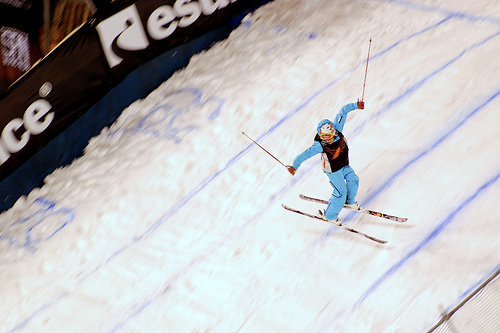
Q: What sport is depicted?
A: Skiing.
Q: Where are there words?
A: Wall on left.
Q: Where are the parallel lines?
A: In the snow.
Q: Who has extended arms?
A: Skier.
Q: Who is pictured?
A: A skier.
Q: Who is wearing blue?
A: The skier.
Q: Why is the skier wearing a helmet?
A: For protection.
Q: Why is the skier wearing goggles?
A: For protection.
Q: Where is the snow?
A: On the ground.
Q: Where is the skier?
A: In the air.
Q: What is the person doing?
A: Skiing.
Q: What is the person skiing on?
A: Snow.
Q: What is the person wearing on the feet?
A: Skis.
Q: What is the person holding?
A: Ski poles.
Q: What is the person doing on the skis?
A: Jumping in the air.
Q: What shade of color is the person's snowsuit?
A: Pastel blue snowsuit.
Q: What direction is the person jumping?
A: Right.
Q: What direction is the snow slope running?
A: Downhill.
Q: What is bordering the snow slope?
A: Blue and black banner fence.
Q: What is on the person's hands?
A: Gloves.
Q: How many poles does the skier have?
A: 2.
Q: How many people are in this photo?
A: 1.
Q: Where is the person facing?
A: Right.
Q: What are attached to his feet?
A: Skis.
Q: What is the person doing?
A: Skiing.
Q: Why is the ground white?
A: Snow.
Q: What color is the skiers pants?
A: Blue.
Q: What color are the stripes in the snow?
A: Blue.